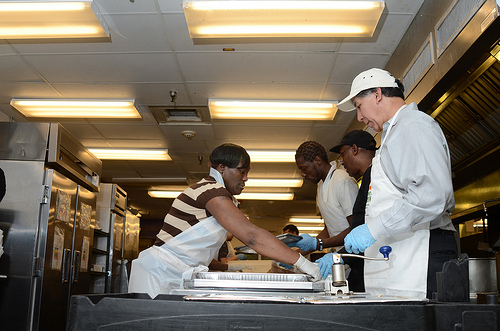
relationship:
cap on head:
[330, 65, 405, 105] [346, 65, 412, 133]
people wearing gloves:
[142, 142, 323, 296] [294, 253, 332, 281]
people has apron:
[142, 142, 323, 296] [143, 221, 227, 286]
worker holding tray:
[292, 136, 360, 246] [231, 232, 302, 253]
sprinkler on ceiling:
[166, 87, 182, 104] [2, 0, 447, 199]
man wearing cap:
[333, 61, 469, 297] [330, 65, 405, 105]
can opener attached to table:
[326, 246, 392, 293] [65, 285, 469, 330]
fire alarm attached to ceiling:
[177, 126, 202, 142] [2, 0, 447, 199]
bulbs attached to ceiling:
[183, 4, 381, 41] [2, 0, 447, 199]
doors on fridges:
[40, 166, 99, 328] [2, 119, 138, 328]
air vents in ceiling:
[154, 105, 207, 124] [2, 0, 447, 199]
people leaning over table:
[142, 142, 323, 296] [65, 285, 469, 330]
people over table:
[156, 65, 459, 296] [65, 285, 469, 330]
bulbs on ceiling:
[183, 4, 381, 41] [2, 0, 447, 199]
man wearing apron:
[333, 61, 469, 297] [362, 149, 431, 288]